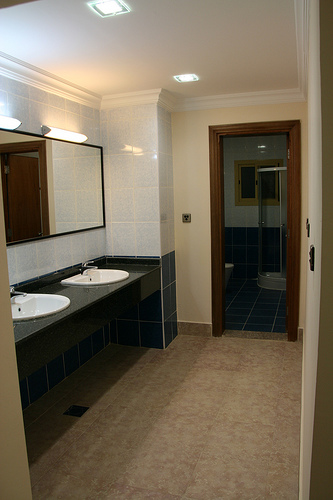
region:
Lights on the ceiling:
[88, 0, 197, 83]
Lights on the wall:
[0, 115, 87, 142]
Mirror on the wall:
[1, 130, 106, 247]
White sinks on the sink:
[11, 269, 128, 319]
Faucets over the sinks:
[10, 260, 98, 304]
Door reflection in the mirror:
[4, 153, 40, 241]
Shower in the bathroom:
[257, 165, 288, 291]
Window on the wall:
[237, 162, 276, 205]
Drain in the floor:
[59, 401, 89, 418]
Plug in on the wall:
[182, 213, 191, 222]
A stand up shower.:
[257, 169, 290, 290]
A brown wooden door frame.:
[208, 123, 298, 341]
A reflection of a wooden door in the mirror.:
[3, 139, 50, 243]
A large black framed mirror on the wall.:
[0, 127, 106, 244]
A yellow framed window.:
[233, 162, 280, 207]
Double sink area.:
[10, 256, 159, 378]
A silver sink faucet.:
[79, 258, 98, 276]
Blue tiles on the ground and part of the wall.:
[225, 226, 290, 332]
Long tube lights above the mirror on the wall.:
[0, 115, 91, 142]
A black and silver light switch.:
[180, 211, 191, 222]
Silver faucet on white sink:
[79, 257, 98, 277]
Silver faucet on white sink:
[9, 284, 28, 304]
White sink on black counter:
[59, 265, 127, 282]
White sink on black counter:
[8, 291, 71, 319]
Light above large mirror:
[38, 121, 87, 142]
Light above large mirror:
[0, 110, 23, 130]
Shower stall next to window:
[253, 164, 285, 291]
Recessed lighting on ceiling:
[171, 71, 198, 83]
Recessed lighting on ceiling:
[83, 0, 132, 18]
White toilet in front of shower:
[224, 258, 236, 292]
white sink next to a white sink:
[59, 264, 127, 288]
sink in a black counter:
[10, 261, 161, 377]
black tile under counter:
[138, 292, 163, 319]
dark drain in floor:
[63, 401, 86, 418]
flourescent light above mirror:
[41, 125, 87, 144]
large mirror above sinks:
[1, 128, 106, 248]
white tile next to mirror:
[109, 187, 133, 223]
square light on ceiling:
[172, 73, 198, 84]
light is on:
[0, 115, 21, 130]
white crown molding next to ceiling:
[0, 0, 313, 111]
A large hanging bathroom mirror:
[0, 127, 105, 245]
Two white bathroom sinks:
[8, 260, 129, 335]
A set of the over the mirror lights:
[1, 114, 87, 143]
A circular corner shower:
[255, 166, 287, 292]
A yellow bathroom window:
[234, 156, 283, 204]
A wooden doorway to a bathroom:
[207, 119, 302, 343]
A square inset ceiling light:
[170, 72, 198, 82]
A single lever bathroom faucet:
[79, 260, 98, 274]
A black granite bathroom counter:
[9, 258, 162, 382]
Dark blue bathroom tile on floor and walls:
[221, 225, 288, 334]